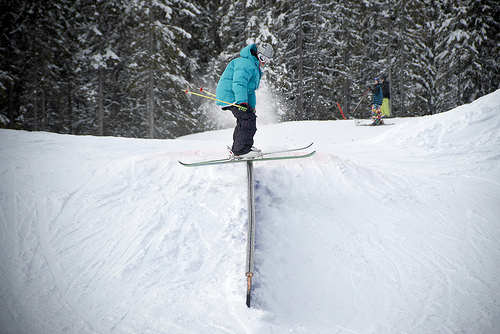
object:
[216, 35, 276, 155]
person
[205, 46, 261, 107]
jacket